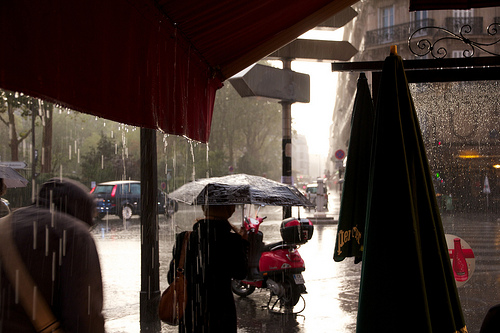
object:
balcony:
[353, 19, 498, 93]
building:
[327, 0, 500, 333]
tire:
[119, 206, 133, 221]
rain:
[2, 89, 211, 329]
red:
[4, 5, 199, 125]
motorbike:
[240, 205, 314, 315]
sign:
[263, 38, 357, 62]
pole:
[278, 102, 294, 287]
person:
[0, 208, 98, 332]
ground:
[406, 113, 446, 158]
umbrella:
[484, 177, 491, 209]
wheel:
[230, 278, 255, 296]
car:
[93, 181, 179, 218]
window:
[404, 16, 496, 66]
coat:
[164, 218, 265, 332]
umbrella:
[167, 174, 317, 239]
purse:
[157, 232, 190, 325]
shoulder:
[175, 230, 195, 249]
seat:
[255, 241, 285, 253]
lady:
[165, 186, 265, 333]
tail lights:
[110, 185, 116, 197]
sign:
[231, 64, 310, 105]